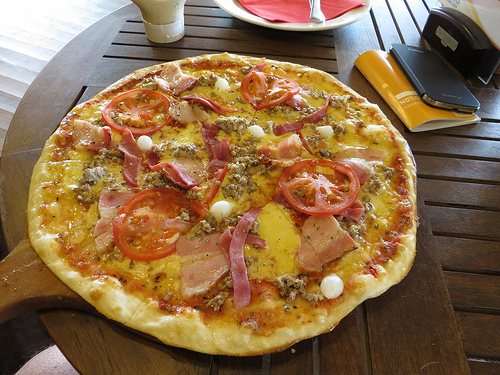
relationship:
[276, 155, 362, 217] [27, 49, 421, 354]
tomato top of pizza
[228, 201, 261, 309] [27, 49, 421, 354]
ham top of pizza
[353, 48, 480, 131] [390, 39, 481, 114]
book under cellphone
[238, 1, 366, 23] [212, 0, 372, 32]
napkin on plate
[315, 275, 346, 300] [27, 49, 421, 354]
ball on pizza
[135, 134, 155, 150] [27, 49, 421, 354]
ball on pizza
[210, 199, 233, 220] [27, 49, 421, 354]
ball on pizza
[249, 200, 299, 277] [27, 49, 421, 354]
cheese on pizza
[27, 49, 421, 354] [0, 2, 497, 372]
pizza on table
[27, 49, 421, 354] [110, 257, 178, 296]
pizza with cheese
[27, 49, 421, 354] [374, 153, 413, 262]
pizza with sauce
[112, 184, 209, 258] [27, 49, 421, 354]
tomato on pizza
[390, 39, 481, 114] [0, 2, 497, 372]
cellphone on table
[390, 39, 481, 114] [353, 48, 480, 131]
cellphone on book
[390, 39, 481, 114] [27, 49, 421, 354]
cellphone near pizza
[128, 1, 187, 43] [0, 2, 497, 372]
cup on table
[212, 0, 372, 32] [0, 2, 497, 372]
plate on table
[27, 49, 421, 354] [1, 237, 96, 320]
pizza on board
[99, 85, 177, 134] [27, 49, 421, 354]
tomato on pizza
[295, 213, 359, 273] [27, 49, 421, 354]
meat on pizza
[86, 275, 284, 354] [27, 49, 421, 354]
crust of pizza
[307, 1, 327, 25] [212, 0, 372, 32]
silverware on plate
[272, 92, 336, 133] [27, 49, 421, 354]
bacon on pizza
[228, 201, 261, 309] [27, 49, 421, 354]
ham on pizza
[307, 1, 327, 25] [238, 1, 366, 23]
silverware on napkin